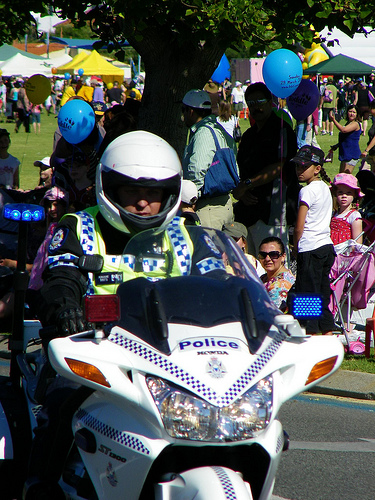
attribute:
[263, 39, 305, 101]
balloon — blue, floating, inflated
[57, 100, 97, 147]
balloon — blue, floating, inflated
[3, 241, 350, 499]
motorcycle — white, blue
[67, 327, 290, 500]
stripe — checkered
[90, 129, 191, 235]
helmet — white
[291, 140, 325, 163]
hat — black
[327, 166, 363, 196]
hat — pink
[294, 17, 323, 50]
balloon — yellow, floating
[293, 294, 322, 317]
light — small, blue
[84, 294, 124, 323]
light — small, red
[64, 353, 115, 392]
light — orange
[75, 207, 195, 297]
safety vest — fluorescent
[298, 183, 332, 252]
shirt — white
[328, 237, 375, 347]
stroller — pink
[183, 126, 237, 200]
bag — blue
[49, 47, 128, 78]
awning — yellow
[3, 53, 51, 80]
awning — white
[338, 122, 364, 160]
top — blue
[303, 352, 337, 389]
light — orange